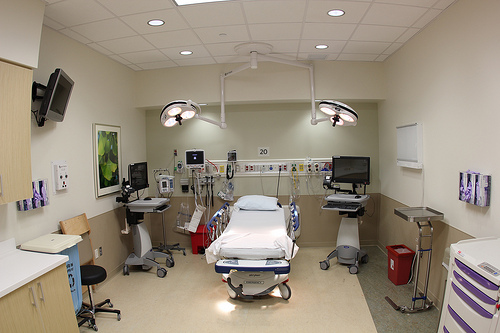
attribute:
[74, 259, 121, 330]
stool — wheeled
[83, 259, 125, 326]
stool — black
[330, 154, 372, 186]
monitor screen — pictured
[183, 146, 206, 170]
monitor screen — pictured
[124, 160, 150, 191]
monitor screen — pictured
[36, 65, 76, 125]
monitor screen — pictured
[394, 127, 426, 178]
screen — lit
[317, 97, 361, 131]
light — moveable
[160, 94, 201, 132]
light — moveable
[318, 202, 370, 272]
stand — rolling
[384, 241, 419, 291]
trash can — red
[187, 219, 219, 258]
trash can — red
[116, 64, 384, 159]
lamps — bog light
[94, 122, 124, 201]
picture — hanging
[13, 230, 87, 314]
bin — tall, light-blue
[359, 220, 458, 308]
can — trash, red, narrow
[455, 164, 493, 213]
boxes — cardboard, glove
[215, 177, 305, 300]
hospital bed — pictured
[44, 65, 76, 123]
tv — flat panel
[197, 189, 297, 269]
bed — mobile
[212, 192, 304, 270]
bed — medical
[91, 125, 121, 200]
picture — framed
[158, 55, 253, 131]
lights —  Two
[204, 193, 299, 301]
bed —  Patient's, hospital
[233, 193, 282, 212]
pillow — white